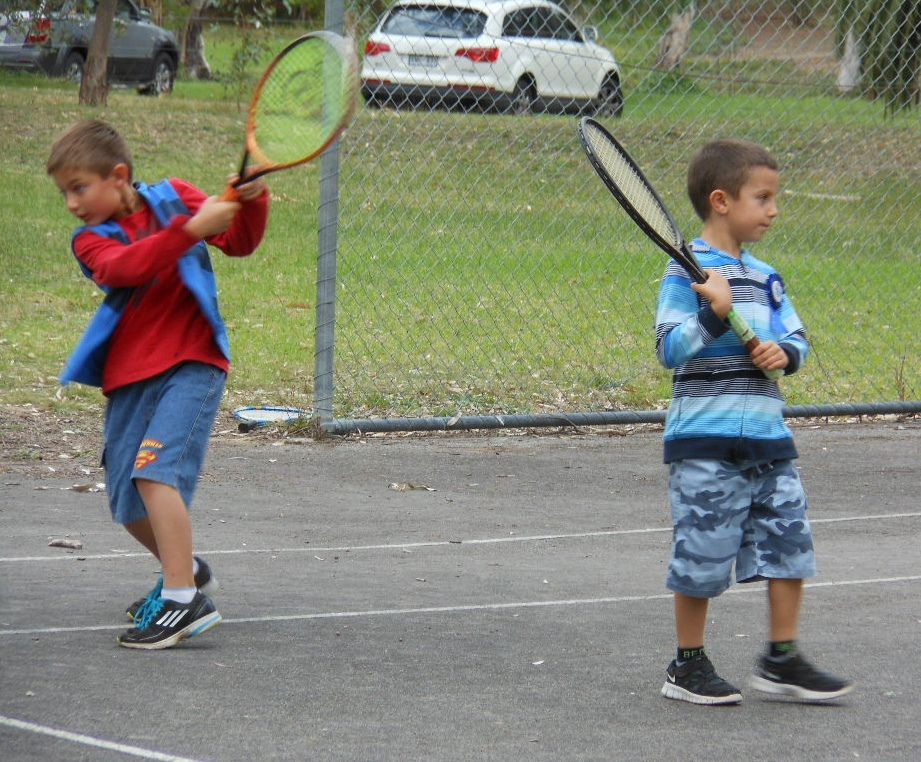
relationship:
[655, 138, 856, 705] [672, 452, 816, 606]
boy wearing shorts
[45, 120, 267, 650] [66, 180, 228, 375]
boy wearing vest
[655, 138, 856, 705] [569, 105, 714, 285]
boy with racket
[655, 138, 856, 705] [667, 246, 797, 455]
boy with shirt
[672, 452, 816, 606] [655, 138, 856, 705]
shorts on boy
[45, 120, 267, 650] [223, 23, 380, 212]
boy with racket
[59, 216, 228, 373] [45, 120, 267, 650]
shirt on boy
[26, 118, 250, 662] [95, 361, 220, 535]
boy wearing shorts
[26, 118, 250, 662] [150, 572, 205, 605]
boy wearing socks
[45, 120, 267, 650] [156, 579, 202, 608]
boy wearing sock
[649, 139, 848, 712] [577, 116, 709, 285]
boy holding racket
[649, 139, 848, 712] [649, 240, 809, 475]
boy wearing shirt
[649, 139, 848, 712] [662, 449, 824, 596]
boy wearing shorts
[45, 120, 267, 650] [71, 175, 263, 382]
boy with shirt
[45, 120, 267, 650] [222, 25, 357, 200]
boy holding racket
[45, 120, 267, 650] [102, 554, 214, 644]
boy wearing shoes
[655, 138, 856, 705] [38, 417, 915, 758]
boy standing on court